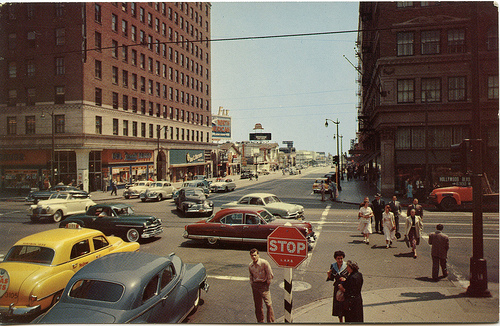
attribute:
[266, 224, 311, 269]
stop sign — red, hexagon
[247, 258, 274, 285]
shirt — tan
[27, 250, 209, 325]
car — grey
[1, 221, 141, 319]
taxi cab — yellow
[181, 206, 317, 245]
car — red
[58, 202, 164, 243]
car — green, dark green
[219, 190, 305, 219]
car — white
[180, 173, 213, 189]
car — light blue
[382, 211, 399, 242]
dress — white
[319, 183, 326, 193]
shirt — pink